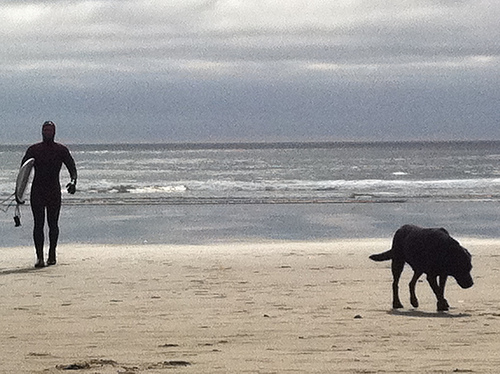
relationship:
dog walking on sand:
[369, 215, 476, 314] [2, 198, 497, 372]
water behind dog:
[0, 140, 498, 244] [368, 222, 474, 316]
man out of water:
[18, 121, 78, 266] [231, 144, 308, 179]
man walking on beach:
[18, 121, 78, 266] [0, 0, 498, 372]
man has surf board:
[18, 121, 78, 266] [12, 156, 35, 202]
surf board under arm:
[12, 156, 35, 202] [63, 157, 82, 203]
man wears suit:
[17, 115, 67, 271] [14, 106, 91, 273]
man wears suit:
[18, 121, 78, 266] [19, 120, 77, 269]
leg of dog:
[408, 270, 419, 307] [368, 222, 474, 316]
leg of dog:
[436, 270, 448, 312] [368, 222, 474, 316]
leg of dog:
[423, 271, 452, 309] [368, 222, 474, 316]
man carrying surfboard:
[18, 121, 78, 266] [6, 152, 29, 211]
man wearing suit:
[18, 121, 78, 266] [19, 120, 77, 269]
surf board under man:
[9, 163, 61, 217] [19, 123, 99, 258]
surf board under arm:
[9, 163, 61, 217] [55, 137, 103, 195]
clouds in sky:
[286, 24, 405, 111] [0, 0, 498, 140]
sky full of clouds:
[108, 19, 448, 137] [1, 7, 490, 94]